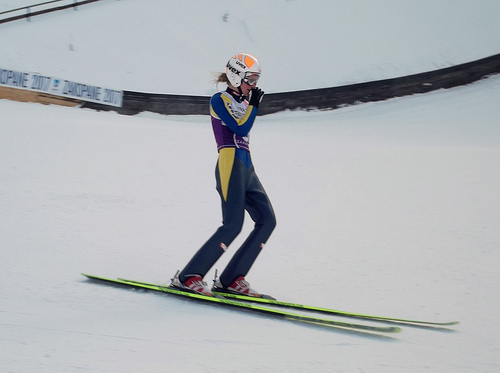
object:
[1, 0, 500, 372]
snow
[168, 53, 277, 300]
person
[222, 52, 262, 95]
helmet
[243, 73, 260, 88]
goggles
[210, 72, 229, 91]
hair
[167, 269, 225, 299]
shoe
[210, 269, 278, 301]
shoe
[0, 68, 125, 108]
sign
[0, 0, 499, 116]
gate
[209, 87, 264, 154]
top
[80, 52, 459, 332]
skiing outfit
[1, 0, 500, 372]
ground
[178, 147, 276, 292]
pants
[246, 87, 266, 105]
hand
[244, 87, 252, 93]
mouth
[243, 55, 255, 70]
shape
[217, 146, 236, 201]
triangle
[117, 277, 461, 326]
ski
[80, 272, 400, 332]
ski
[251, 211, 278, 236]
knee